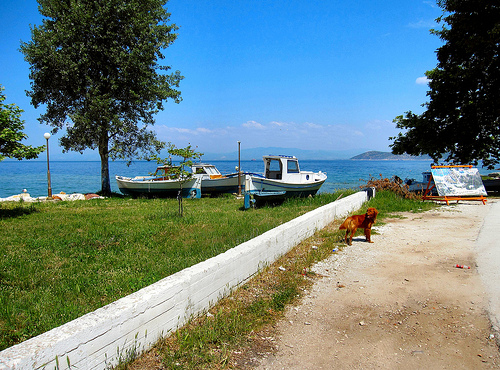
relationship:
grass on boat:
[81, 221, 162, 276] [234, 144, 321, 208]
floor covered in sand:
[350, 276, 459, 357] [284, 337, 313, 358]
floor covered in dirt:
[350, 276, 459, 357] [399, 313, 411, 327]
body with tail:
[339, 208, 381, 246] [341, 218, 353, 229]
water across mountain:
[334, 166, 361, 180] [350, 150, 390, 162]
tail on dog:
[333, 215, 348, 232] [339, 205, 380, 247]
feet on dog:
[365, 234, 375, 247] [340, 204, 381, 254]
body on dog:
[338, 212, 372, 229] [337, 205, 381, 249]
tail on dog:
[339, 216, 353, 230] [333, 204, 381, 247]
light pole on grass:
[46, 139, 52, 198] [81, 221, 221, 283]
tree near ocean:
[15, 1, 183, 198] [336, 160, 412, 170]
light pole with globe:
[44, 136, 49, 198] [44, 132, 52, 139]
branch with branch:
[361, 173, 423, 200] [359, 173, 422, 200]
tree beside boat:
[15, 1, 183, 198] [222, 139, 379, 239]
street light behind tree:
[23, 123, 85, 207] [15, 1, 183, 198]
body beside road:
[339, 208, 381, 246] [200, 150, 480, 367]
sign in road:
[433, 168, 485, 195] [268, 184, 471, 368]